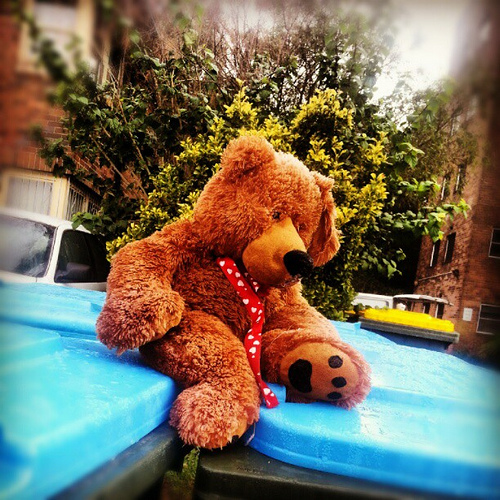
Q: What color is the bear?
A: Brown.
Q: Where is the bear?
A: Sitting outside.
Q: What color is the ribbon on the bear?
A: Red and white.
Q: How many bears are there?
A: 1.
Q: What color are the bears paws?
A: Black and brown.